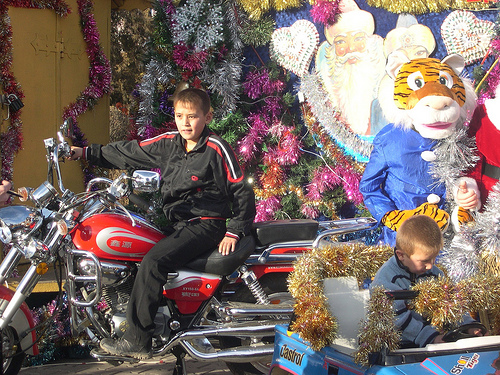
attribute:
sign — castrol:
[277, 343, 308, 368]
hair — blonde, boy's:
[394, 215, 442, 258]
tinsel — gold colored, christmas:
[292, 243, 499, 367]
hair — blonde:
[386, 215, 442, 262]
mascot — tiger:
[345, 56, 492, 218]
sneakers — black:
[97, 331, 158, 364]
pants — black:
[100, 219, 224, 359]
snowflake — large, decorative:
[170, 0, 224, 53]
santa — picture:
[316, 1, 386, 137]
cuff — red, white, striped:
[221, 229, 265, 249]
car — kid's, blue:
[257, 204, 398, 281]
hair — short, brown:
[395, 215, 440, 248]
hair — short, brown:
[175, 87, 211, 108]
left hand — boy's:
[217, 235, 243, 250]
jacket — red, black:
[83, 130, 256, 239]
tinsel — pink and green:
[47, 0, 112, 187]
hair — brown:
[165, 85, 213, 115]